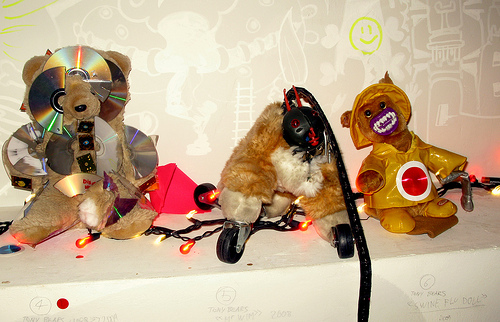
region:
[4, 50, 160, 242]
Bear sliced with dvds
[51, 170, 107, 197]
Broken dvd or cd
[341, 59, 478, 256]
stuffed money with purple lips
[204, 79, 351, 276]
Stuffed animal with mask on wheels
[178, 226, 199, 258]
orange light bulb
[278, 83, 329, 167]
black and red mask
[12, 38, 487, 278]
three stuffed animals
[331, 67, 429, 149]
stuffed animal head with yellow hat and sharp teeth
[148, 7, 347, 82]
white wallpaper with white designs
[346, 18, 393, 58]
yellow happy face on wall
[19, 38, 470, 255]
Small plush animals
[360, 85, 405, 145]
Face is grinning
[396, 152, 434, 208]
White and red target on animal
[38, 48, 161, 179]
Broken CDs on animal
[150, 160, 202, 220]
Red paper in background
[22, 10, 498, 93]
White wall behind toys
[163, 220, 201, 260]
Red light next to animals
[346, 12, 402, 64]
Yellow smiley face on wall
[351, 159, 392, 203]
Left arm of animal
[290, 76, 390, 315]
Black rope is thick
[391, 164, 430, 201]
round shiny red and white design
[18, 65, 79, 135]
a broken CD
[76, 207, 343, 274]
red Christmas lights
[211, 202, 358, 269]
two wheels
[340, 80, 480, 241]
a plushie in a yellow raincoat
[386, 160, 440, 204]
a red and white circle on a yellow raincoat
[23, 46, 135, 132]
broken CDs on the head of a teddy bear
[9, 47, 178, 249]
a teddy bear sitting down on a white shelf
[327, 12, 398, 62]
a yellow smiley face on the wall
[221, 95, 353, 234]
an orange and white plushie on a shelf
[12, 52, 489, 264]
three plushies on a white shelf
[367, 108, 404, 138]
Purple and white monster teeth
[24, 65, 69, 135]
Broken CD half on bear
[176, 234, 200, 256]
Orange light on the table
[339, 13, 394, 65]
Yellow smiley face on the wall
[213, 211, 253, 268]
Black wheel attached to stuffed animal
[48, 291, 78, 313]
Red circle on white cloth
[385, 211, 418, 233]
Yellow plastic rain shoe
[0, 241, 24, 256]
Blue circle on the white cloth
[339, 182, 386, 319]
Long black tubing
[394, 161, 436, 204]
Red and white reflector on yellow jacket